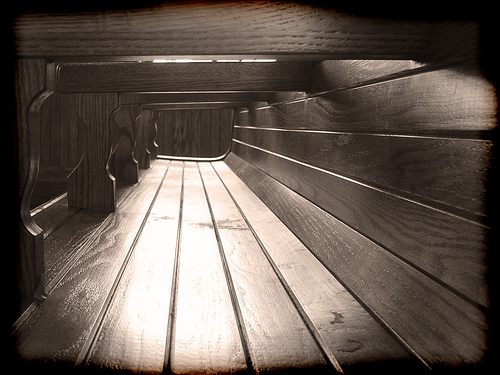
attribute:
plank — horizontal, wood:
[41, 149, 184, 356]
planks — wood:
[224, 32, 498, 372]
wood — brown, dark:
[370, 85, 469, 232]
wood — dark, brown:
[127, 231, 230, 319]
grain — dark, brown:
[182, 196, 212, 231]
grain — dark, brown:
[148, 196, 178, 229]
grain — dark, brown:
[266, 176, 309, 222]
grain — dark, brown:
[393, 198, 445, 266]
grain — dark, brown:
[379, 269, 439, 334]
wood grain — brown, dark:
[245, 148, 411, 320]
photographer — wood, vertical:
[150, 155, 251, 354]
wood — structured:
[140, 160, 334, 361]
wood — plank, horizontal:
[3, 8, 492, 65]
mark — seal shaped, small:
[325, 300, 360, 345]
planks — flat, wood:
[80, 111, 399, 333]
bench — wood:
[16, 0, 497, 374]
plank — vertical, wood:
[59, 88, 129, 219]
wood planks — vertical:
[13, 59, 164, 316]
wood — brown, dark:
[60, 286, 117, 325]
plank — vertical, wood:
[13, 54, 57, 311]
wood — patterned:
[285, 114, 449, 259]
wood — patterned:
[135, 145, 284, 322]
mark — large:
[115, 200, 247, 234]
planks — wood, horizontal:
[212, 75, 482, 359]